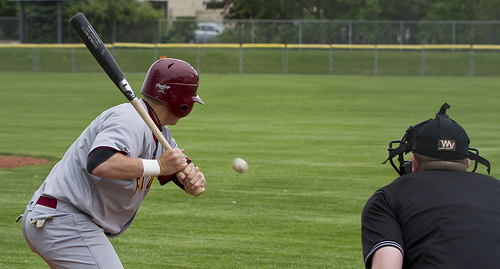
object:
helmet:
[140, 58, 204, 118]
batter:
[19, 57, 204, 269]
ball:
[230, 157, 248, 173]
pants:
[22, 193, 125, 269]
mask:
[386, 123, 492, 175]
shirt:
[360, 170, 500, 268]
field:
[2, 73, 498, 269]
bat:
[68, 12, 206, 197]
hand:
[155, 148, 188, 176]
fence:
[1, 16, 499, 77]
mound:
[1, 153, 47, 169]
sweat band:
[141, 158, 160, 177]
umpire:
[359, 102, 498, 269]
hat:
[410, 117, 472, 161]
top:
[0, 42, 499, 51]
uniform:
[15, 98, 191, 237]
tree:
[65, 2, 160, 44]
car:
[193, 20, 225, 43]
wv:
[438, 140, 455, 150]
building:
[164, 0, 238, 43]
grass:
[1, 77, 497, 266]